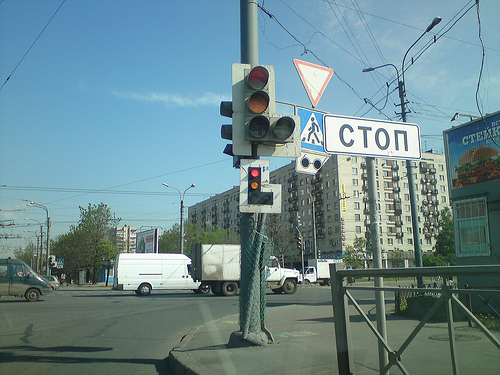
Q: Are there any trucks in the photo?
A: Yes, there is a truck.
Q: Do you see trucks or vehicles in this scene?
A: Yes, there is a truck.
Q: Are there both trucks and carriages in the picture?
A: No, there is a truck but no carriages.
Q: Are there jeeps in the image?
A: No, there are no jeeps.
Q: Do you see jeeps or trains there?
A: No, there are no jeeps or trains.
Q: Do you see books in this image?
A: No, there are no books.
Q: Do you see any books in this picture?
A: No, there are no books.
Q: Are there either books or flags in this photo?
A: No, there are no books or flags.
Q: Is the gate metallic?
A: Yes, the gate is metallic.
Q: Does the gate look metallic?
A: Yes, the gate is metallic.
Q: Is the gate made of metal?
A: Yes, the gate is made of metal.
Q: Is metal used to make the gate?
A: Yes, the gate is made of metal.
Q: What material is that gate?
A: The gate is made of metal.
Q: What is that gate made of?
A: The gate is made of metal.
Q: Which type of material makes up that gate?
A: The gate is made of metal.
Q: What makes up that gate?
A: The gate is made of metal.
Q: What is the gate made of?
A: The gate is made of metal.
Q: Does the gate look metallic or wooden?
A: The gate is metallic.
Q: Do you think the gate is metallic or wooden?
A: The gate is metallic.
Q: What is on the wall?
A: The sign is on the wall.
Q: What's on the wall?
A: The sign is on the wall.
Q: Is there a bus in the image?
A: No, there are no buses.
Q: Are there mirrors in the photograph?
A: No, there are no mirrors.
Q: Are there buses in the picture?
A: No, there are no buses.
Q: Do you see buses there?
A: No, there are no buses.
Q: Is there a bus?
A: No, there are no buses.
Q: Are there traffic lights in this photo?
A: Yes, there is a traffic light.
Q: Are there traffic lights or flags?
A: Yes, there is a traffic light.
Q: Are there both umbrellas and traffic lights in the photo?
A: No, there is a traffic light but no umbrellas.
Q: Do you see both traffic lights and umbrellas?
A: No, there is a traffic light but no umbrellas.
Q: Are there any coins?
A: No, there are no coins.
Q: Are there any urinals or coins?
A: No, there are no coins or urinals.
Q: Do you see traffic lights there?
A: Yes, there is a traffic light.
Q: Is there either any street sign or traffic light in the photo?
A: Yes, there is a traffic light.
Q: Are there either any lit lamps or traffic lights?
A: Yes, there is a lit traffic light.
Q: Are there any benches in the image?
A: No, there are no benches.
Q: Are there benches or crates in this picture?
A: No, there are no benches or crates.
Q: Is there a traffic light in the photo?
A: Yes, there is a traffic light.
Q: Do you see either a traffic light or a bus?
A: Yes, there is a traffic light.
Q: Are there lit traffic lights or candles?
A: Yes, there is a lit traffic light.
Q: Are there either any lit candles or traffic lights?
A: Yes, there is a lit traffic light.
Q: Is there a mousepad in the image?
A: No, there are no mouse pads.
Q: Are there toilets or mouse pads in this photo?
A: No, there are no mouse pads or toilets.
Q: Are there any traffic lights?
A: Yes, there is a traffic light.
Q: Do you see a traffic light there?
A: Yes, there is a traffic light.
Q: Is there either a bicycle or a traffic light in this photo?
A: Yes, there is a traffic light.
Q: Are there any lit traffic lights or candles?
A: Yes, there is a lit traffic light.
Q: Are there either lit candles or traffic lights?
A: Yes, there is a lit traffic light.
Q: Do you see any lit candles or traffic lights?
A: Yes, there is a lit traffic light.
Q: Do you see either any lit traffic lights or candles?
A: Yes, there is a lit traffic light.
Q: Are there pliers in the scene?
A: No, there are no pliers.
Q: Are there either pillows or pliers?
A: No, there are no pliers or pillows.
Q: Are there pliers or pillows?
A: No, there are no pliers or pillows.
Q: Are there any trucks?
A: Yes, there is a truck.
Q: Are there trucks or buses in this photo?
A: Yes, there is a truck.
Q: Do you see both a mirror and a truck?
A: No, there is a truck but no mirrors.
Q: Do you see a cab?
A: No, there are no taxis.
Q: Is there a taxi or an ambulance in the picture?
A: No, there are no taxis or ambulances.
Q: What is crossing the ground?
A: The truck is crossing the ground.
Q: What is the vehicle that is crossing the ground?
A: The vehicle is a truck.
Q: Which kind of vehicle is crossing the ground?
A: The vehicle is a truck.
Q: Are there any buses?
A: No, there are no buses.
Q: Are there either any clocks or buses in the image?
A: No, there are no buses or clocks.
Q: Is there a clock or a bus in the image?
A: No, there are no buses or clocks.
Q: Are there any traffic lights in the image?
A: Yes, there is a traffic light.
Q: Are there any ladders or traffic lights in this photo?
A: Yes, there is a traffic light.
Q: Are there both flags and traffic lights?
A: No, there is a traffic light but no flags.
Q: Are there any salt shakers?
A: No, there are no salt shakers.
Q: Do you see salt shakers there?
A: No, there are no salt shakers.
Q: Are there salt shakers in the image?
A: No, there are no salt shakers.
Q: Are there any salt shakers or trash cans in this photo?
A: No, there are no salt shakers or trash cans.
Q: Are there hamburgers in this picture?
A: Yes, there is a hamburger.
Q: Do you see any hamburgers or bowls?
A: Yes, there is a hamburger.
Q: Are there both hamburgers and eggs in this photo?
A: No, there is a hamburger but no eggs.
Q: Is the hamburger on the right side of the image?
A: Yes, the hamburger is on the right of the image.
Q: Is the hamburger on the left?
A: No, the hamburger is on the right of the image.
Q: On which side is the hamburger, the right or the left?
A: The hamburger is on the right of the image.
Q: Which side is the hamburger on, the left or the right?
A: The hamburger is on the right of the image.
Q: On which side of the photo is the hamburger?
A: The hamburger is on the right of the image.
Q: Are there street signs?
A: Yes, there is a street sign.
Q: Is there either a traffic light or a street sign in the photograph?
A: Yes, there is a street sign.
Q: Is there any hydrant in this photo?
A: No, there are no fire hydrants.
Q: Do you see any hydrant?
A: No, there are no fire hydrants.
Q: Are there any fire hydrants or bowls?
A: No, there are no fire hydrants or bowls.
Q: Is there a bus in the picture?
A: No, there are no buses.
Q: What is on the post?
A: The sign is on the post.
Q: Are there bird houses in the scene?
A: No, there are no bird houses.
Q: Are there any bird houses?
A: No, there are no bird houses.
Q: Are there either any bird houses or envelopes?
A: No, there are no bird houses or envelopes.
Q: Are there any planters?
A: No, there are no planters.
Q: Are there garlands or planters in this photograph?
A: No, there are no planters or garlands.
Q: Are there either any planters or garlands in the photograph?
A: No, there are no planters or garlands.